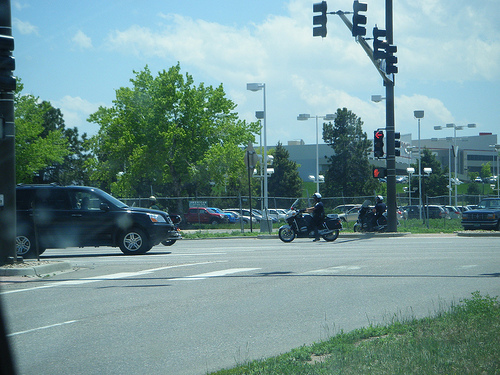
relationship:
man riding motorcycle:
[364, 193, 387, 230] [352, 195, 400, 235]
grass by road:
[191, 291, 499, 374] [1, 238, 499, 374]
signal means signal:
[371, 164, 387, 180] [372, 167, 384, 179]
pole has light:
[261, 83, 271, 219] [246, 79, 267, 95]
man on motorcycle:
[304, 190, 324, 244] [274, 193, 343, 244]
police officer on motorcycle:
[364, 193, 387, 230] [352, 195, 400, 235]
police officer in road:
[304, 190, 324, 244] [1, 238, 499, 374]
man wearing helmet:
[364, 193, 387, 230] [375, 193, 386, 204]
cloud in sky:
[71, 29, 92, 52] [10, 2, 499, 175]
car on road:
[13, 183, 186, 258] [1, 238, 499, 374]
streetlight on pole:
[394, 130, 405, 161] [384, 1, 400, 233]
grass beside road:
[176, 220, 471, 241] [1, 238, 499, 374]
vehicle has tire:
[13, 183, 186, 258] [12, 226, 38, 261]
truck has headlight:
[459, 196, 499, 234] [485, 212, 496, 219]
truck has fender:
[459, 196, 499, 234] [459, 220, 499, 230]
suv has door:
[13, 183, 186, 258] [70, 186, 118, 245]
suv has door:
[13, 183, 186, 258] [27, 187, 71, 246]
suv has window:
[13, 183, 186, 258] [73, 188, 111, 210]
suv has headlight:
[13, 183, 186, 258] [147, 210, 168, 226]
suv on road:
[13, 183, 186, 258] [1, 238, 499, 374]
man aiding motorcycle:
[304, 190, 324, 244] [274, 193, 343, 244]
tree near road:
[80, 61, 262, 230] [1, 238, 499, 374]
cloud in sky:
[13, 18, 38, 38] [10, 2, 499, 175]